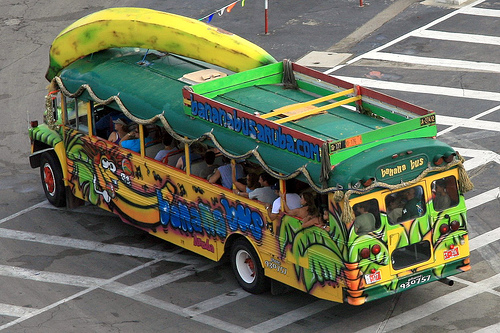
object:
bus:
[30, 5, 472, 309]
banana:
[46, 8, 280, 83]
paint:
[39, 125, 466, 305]